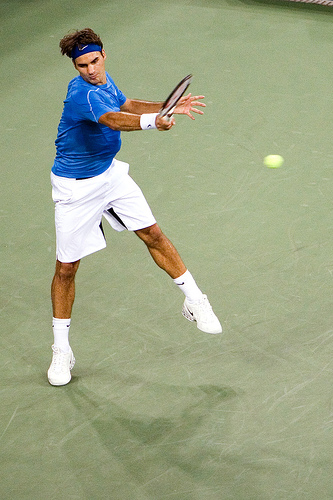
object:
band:
[71, 44, 102, 59]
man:
[46, 28, 223, 387]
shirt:
[51, 72, 126, 179]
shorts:
[49, 157, 157, 263]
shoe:
[181, 294, 223, 335]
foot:
[182, 295, 223, 336]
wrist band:
[139, 113, 160, 131]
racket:
[157, 73, 193, 123]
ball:
[263, 153, 284, 169]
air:
[2, 1, 332, 500]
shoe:
[47, 345, 76, 388]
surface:
[1, 1, 332, 500]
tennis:
[157, 74, 192, 122]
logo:
[176, 281, 184, 285]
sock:
[172, 268, 203, 300]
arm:
[74, 95, 159, 132]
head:
[59, 27, 109, 84]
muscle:
[148, 246, 170, 271]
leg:
[106, 179, 222, 335]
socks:
[51, 318, 72, 349]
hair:
[58, 28, 104, 59]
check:
[185, 304, 193, 317]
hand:
[174, 92, 207, 121]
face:
[76, 51, 104, 84]